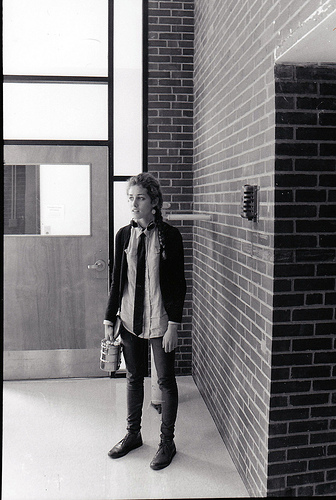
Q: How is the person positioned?
A: Standing.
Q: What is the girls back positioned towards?
A: Brick wall.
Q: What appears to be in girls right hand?
A: Lunch box.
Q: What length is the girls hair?
A: Long.